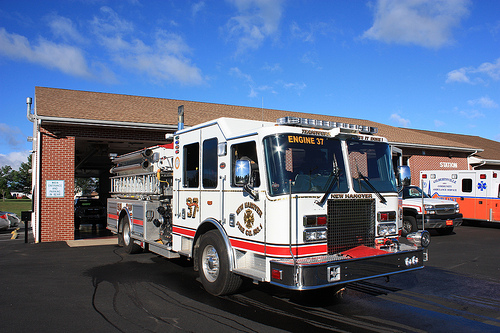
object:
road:
[4, 208, 499, 331]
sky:
[1, 2, 499, 161]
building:
[31, 84, 480, 261]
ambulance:
[114, 124, 382, 285]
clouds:
[137, 53, 191, 85]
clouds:
[14, 40, 95, 83]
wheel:
[114, 215, 132, 247]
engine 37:
[277, 132, 337, 153]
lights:
[303, 225, 328, 241]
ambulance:
[105, 101, 432, 297]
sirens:
[278, 114, 378, 134]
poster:
[47, 180, 63, 197]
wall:
[42, 133, 74, 240]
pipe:
[177, 99, 187, 131]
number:
[316, 137, 326, 144]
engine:
[167, 117, 421, 297]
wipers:
[315, 171, 336, 204]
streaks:
[270, 294, 490, 330]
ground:
[3, 290, 496, 330]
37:
[185, 195, 200, 218]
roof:
[38, 85, 482, 152]